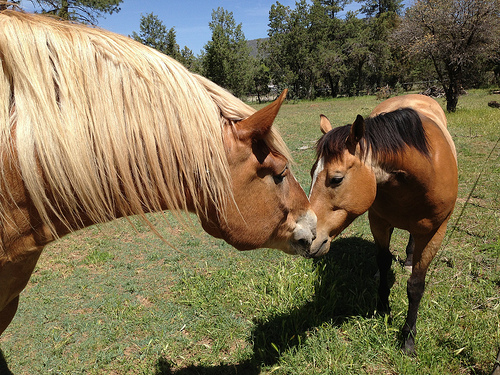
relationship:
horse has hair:
[0, 0, 320, 374] [5, 25, 215, 245]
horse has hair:
[3, 2, 320, 372] [315, 107, 433, 170]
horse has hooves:
[297, 83, 466, 370] [374, 299, 419, 358]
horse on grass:
[295, 92, 460, 359] [210, 256, 372, 343]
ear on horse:
[236, 87, 287, 139] [6, 20, 313, 351]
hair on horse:
[308, 101, 438, 160] [301, 78, 478, 356]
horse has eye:
[295, 92, 460, 359] [329, 174, 341, 184]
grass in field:
[0, 85, 499, 375] [459, 100, 496, 362]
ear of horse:
[314, 109, 335, 140] [264, 78, 469, 334]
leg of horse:
[398, 220, 448, 355] [299, 93, 458, 355]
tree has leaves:
[263, 4, 314, 104] [2, 1, 499, 98]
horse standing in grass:
[295, 92, 460, 359] [83, 230, 481, 373]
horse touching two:
[0, 0, 320, 374] [0, 15, 466, 310]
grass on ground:
[0, 85, 499, 373] [0, 95, 499, 374]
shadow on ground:
[150, 220, 395, 370] [41, 94, 496, 371]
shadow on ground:
[144, 228, 403, 375] [209, 254, 482, 359]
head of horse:
[190, 83, 322, 253] [1, 57, 328, 287]